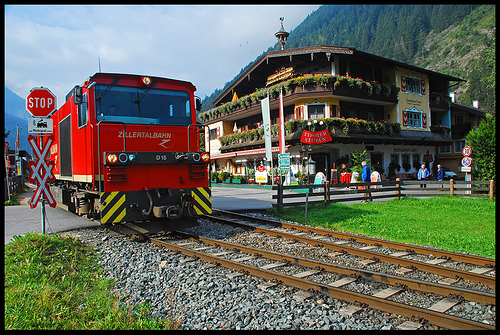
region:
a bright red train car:
[37, 72, 212, 226]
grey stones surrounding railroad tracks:
[95, 211, 494, 327]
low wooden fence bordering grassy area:
[271, 178, 496, 217]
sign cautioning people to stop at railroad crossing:
[27, 86, 57, 234]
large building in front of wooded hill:
[202, 3, 484, 186]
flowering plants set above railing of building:
[200, 71, 398, 149]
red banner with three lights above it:
[300, 118, 332, 145]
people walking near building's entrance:
[305, 147, 447, 195]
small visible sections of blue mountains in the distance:
[6, 85, 28, 151]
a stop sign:
[25, 87, 61, 127]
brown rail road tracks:
[138, 192, 483, 331]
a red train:
[53, 83, 223, 228]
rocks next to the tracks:
[150, 255, 270, 334]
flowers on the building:
[228, 110, 363, 132]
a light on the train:
[108, 152, 123, 162]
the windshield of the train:
[93, 87, 195, 122]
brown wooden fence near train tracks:
[269, 174, 496, 216]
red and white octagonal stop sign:
[26, 86, 58, 118]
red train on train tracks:
[26, 61, 217, 228]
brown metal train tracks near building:
[82, 201, 497, 333]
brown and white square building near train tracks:
[198, 13, 470, 190]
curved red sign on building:
[297, 126, 334, 146]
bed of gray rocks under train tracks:
[51, 208, 497, 333]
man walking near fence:
[358, 158, 374, 205]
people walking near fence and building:
[413, 159, 446, 190]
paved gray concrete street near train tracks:
[1, 176, 498, 253]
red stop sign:
[26, 87, 56, 117]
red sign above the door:
[298, 129, 333, 144]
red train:
[35, 72, 212, 229]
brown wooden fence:
[271, 178, 493, 210]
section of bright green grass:
[264, 193, 494, 256]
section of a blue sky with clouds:
[5, 4, 317, 109]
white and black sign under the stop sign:
[28, 117, 53, 134]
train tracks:
[114, 223, 496, 330]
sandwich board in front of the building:
[311, 170, 326, 191]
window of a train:
[152, 94, 200, 124]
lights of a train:
[99, 136, 129, 165]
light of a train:
[188, 125, 220, 179]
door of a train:
[52, 93, 79, 185]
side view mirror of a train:
[65, 82, 87, 112]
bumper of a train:
[97, 180, 223, 238]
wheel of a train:
[63, 196, 88, 213]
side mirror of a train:
[188, 94, 205, 109]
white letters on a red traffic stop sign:
[22, 85, 52, 115]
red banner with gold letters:
[298, 126, 331, 144]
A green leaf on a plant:
[377, 27, 380, 28]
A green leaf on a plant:
[397, 19, 401, 21]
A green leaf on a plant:
[314, 13, 319, 15]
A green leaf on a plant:
[395, 30, 396, 32]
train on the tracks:
[20, 70, 232, 258]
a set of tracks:
[152, 209, 489, 330]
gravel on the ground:
[105, 230, 250, 328]